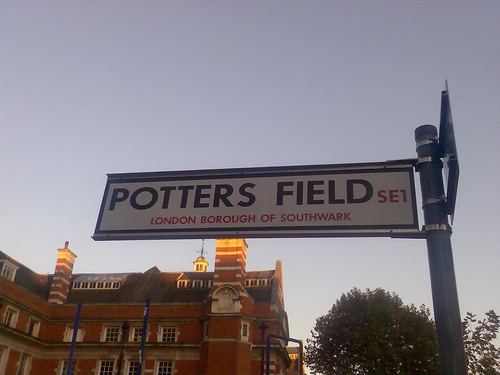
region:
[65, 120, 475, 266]
A street sign in London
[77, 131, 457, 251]
Sign reads Potters Field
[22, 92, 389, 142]
A grey cloudless sky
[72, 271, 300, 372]
Multiple-story brick building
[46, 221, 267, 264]
Sunlight hitting the top of the building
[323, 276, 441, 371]
Tree behind sign post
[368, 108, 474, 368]
Sign is at a corner or intersection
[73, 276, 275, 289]
Windows in the top section of building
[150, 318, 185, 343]
Cream moulding around windows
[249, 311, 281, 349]
Cross on building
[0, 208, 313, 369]
the big building in the back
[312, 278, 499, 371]
the tree near the pole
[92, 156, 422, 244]
the white street sign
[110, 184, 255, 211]
the word POTTERS on the sign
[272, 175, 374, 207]
the word FIELD on the sign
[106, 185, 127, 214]
the letter P on the sign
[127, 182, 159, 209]
the letter O on the sign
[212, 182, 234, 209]
the letter R on the sign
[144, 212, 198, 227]
the word LONDON on the sign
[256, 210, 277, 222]
the word OF on the sign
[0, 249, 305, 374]
a red brick building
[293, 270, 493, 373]
a green tree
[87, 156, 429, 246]
a street sign that says POTTERS FIELD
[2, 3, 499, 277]
a sky with no clouds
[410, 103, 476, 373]
a gray pole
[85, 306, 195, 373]
some windows on buildings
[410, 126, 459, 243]
some silver clamps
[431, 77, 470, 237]
a street sign coming towards the camera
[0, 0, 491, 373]
a scene outside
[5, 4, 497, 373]
a scene happening during the day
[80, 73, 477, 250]
United Kingdom street sign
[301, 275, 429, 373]
Lush green tree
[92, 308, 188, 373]
Set of six windows on brick building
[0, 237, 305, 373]
Large brick church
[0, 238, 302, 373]
Red brick church with twenty nine windows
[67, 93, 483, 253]
Metal street sign in London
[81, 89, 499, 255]
Street sign made of metal in London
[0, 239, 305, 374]
Church with red bricks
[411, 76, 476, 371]
Metal pole with street sign attached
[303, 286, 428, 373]
Leaves on a tree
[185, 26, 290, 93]
sky above the sign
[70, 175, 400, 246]
words on the sign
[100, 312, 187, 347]
window on a building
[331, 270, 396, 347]
tree in the distance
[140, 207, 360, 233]
words under other words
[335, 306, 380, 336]
leaves on the tree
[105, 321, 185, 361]
six different windows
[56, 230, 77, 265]
top of the building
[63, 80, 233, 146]
clear sky with no clouds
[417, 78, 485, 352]
pole holding up the sign